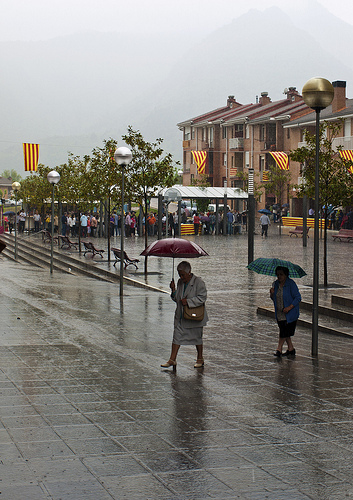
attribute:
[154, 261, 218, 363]
woman — carrying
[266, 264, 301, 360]
woman — walking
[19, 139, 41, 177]
flag — red, yellow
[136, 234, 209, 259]
umbrella — red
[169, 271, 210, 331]
jacket — gray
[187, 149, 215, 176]
flag — hanging 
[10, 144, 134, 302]
lights — tall 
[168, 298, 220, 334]
purse — brown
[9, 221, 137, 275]
benches — long 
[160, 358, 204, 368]
shoes — tan , high heel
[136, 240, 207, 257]
umbrella — red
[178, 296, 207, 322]
purse — brown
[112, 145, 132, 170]
light — round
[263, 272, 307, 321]
jacket — blue